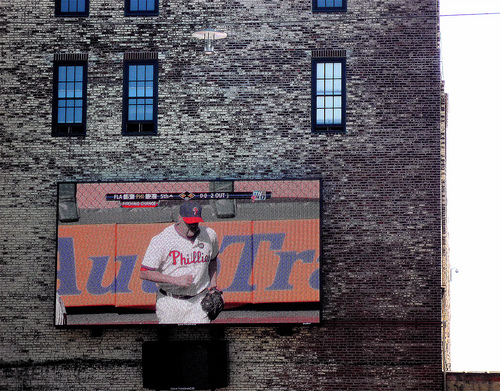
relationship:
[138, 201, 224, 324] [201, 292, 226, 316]
baseball player wearing glove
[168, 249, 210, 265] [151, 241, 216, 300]
letters on shirt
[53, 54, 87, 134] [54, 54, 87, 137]
frame on window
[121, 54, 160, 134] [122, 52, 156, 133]
frame on window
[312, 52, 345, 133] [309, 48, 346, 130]
frame on window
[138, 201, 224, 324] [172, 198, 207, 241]
baseball player has head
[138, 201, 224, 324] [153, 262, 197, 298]
baseball player has hand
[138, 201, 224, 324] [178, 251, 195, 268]
baseball player with letters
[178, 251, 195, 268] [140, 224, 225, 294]
letters on shirt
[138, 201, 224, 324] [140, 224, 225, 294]
baseball player has shirt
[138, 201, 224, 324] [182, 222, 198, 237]
baseball player has face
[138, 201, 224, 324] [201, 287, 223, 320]
baseball player wearing glove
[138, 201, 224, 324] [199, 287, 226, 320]
baseball player has glove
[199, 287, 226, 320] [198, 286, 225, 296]
glove on hand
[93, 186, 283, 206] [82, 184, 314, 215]
scoreboard at top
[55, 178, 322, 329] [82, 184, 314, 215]
screen has top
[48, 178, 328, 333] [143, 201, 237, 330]
screen showing player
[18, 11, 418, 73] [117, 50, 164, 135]
sky reflected in window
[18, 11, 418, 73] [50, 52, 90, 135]
sky reflected in window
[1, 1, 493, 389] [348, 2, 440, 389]
building has brick wall